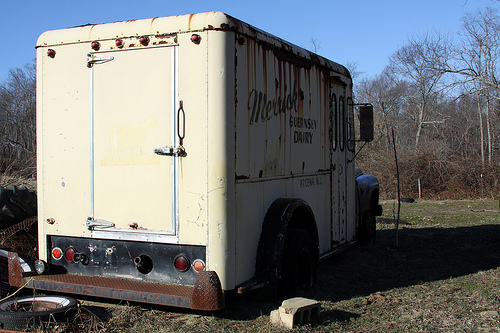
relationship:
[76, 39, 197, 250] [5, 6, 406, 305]
backdoor of truck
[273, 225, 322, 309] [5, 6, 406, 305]
tires on truck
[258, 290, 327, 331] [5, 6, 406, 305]
brick by truck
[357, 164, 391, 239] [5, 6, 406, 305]
front of truck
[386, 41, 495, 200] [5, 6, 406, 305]
trees near truck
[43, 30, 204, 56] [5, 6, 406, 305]
light on top of truck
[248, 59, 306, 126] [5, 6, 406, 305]
company's name on truck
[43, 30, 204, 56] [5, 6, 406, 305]
light on back of truck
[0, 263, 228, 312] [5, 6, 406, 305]
bumper of truck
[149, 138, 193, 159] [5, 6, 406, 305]
handle on truck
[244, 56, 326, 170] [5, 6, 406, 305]
writing on truck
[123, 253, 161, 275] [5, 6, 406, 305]
exhaust on truck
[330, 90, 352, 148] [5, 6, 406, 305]
windows on truck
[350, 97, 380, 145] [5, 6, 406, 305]
mirror on truck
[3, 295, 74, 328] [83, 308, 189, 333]
tire on ground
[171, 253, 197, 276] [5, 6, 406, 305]
light on truck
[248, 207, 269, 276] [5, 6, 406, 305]
leaves on truck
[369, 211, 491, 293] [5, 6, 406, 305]
shadow of truck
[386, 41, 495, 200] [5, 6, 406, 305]
trees in front of truck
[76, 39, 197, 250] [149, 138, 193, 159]
backdoor with handle